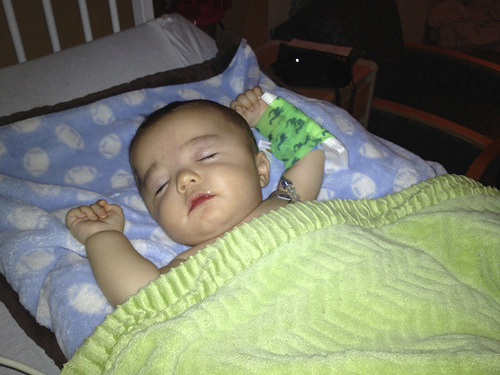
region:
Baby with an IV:
[62, 83, 324, 303]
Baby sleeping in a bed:
[60, 87, 328, 307]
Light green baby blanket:
[58, 172, 498, 372]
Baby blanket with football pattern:
[2, 32, 448, 364]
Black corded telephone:
[269, 40, 359, 120]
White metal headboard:
[1, 0, 155, 70]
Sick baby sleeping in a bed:
[61, 85, 347, 312]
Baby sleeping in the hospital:
[58, 84, 348, 311]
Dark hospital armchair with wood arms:
[269, 3, 498, 179]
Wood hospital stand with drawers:
[247, 35, 377, 133]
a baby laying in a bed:
[75, 80, 395, 352]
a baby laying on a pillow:
[20, 60, 400, 330]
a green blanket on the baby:
[145, 227, 495, 357]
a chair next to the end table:
[306, 30, 498, 168]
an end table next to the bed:
[240, 25, 360, 100]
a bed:
[6, 36, 492, 361]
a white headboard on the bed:
[1, 2, 166, 52]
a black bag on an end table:
[266, 42, 356, 78]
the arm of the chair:
[376, 88, 495, 145]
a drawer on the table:
[343, 94, 371, 116]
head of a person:
[109, 73, 283, 258]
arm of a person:
[76, 218, 157, 296]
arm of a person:
[262, 95, 345, 177]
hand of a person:
[59, 180, 143, 236]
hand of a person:
[217, 75, 293, 136]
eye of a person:
[143, 165, 175, 206]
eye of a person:
[192, 128, 238, 175]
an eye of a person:
[143, 163, 178, 206]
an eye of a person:
[187, 140, 240, 167]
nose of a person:
[172, 165, 217, 199]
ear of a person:
[245, 142, 287, 190]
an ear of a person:
[240, 142, 266, 188]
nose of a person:
[170, 157, 201, 192]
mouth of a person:
[181, 185, 243, 229]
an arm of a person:
[102, 245, 182, 301]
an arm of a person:
[258, 112, 341, 180]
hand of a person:
[45, 188, 159, 258]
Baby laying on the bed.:
[29, 80, 444, 345]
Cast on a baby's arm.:
[215, 73, 347, 170]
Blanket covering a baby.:
[38, 186, 495, 372]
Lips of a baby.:
[180, 189, 225, 214]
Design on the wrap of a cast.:
[283, 118, 306, 135]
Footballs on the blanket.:
[51, 153, 105, 198]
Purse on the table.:
[267, 33, 392, 103]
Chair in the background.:
[283, 3, 493, 166]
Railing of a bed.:
[13, 8, 128, 46]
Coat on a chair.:
[427, 7, 497, 46]